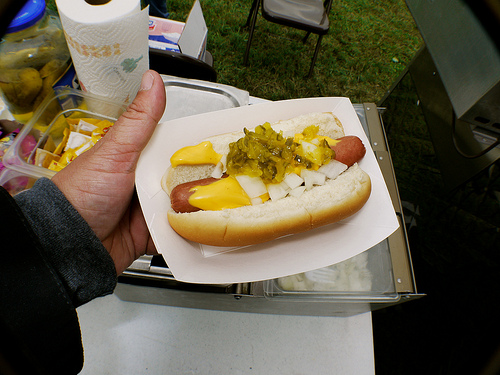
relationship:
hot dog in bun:
[171, 136, 365, 211] [164, 110, 372, 248]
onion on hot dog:
[235, 174, 268, 200] [171, 136, 365, 211]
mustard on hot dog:
[170, 125, 343, 210] [171, 136, 365, 211]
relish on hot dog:
[226, 122, 336, 186] [171, 136, 365, 211]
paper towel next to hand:
[55, 2, 151, 115] [51, 70, 160, 282]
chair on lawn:
[243, 0, 332, 78] [45, 0, 426, 107]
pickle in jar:
[2, 66, 42, 113] [2, 1, 89, 142]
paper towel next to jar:
[55, 2, 151, 115] [2, 1, 89, 142]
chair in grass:
[243, 0, 332, 78] [46, 0, 425, 107]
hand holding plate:
[51, 70, 160, 282] [135, 97, 401, 286]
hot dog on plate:
[171, 136, 365, 211] [135, 97, 401, 286]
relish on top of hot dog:
[226, 122, 336, 186] [171, 136, 365, 211]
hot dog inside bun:
[171, 136, 365, 211] [164, 110, 372, 248]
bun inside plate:
[164, 110, 372, 248] [135, 97, 401, 286]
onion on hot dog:
[282, 170, 303, 192] [171, 136, 365, 211]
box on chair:
[139, 0, 209, 65] [149, 46, 219, 82]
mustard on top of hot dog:
[170, 125, 343, 210] [171, 136, 365, 211]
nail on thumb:
[136, 71, 155, 93] [89, 71, 166, 238]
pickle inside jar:
[2, 66, 42, 113] [2, 1, 89, 142]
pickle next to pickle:
[2, 66, 42, 113] [2, 45, 67, 70]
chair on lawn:
[149, 46, 219, 82] [45, 0, 426, 107]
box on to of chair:
[139, 0, 209, 65] [149, 46, 219, 82]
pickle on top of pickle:
[2, 45, 67, 70] [2, 66, 42, 113]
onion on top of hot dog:
[299, 165, 328, 187] [171, 136, 365, 211]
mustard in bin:
[35, 146, 62, 169] [4, 85, 133, 175]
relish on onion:
[226, 122, 336, 186] [235, 174, 268, 200]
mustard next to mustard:
[35, 146, 62, 169] [64, 132, 90, 154]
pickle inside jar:
[2, 45, 67, 70] [2, 1, 89, 142]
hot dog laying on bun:
[171, 136, 365, 211] [164, 110, 372, 248]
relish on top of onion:
[226, 122, 336, 186] [235, 174, 268, 200]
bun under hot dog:
[164, 110, 372, 248] [171, 136, 365, 211]